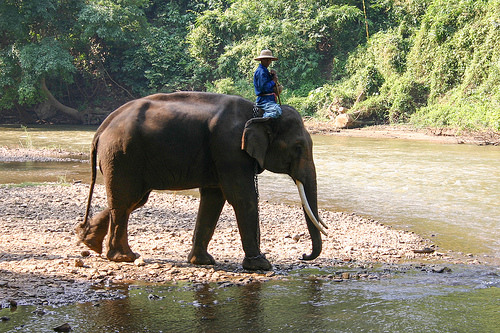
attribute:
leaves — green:
[0, 0, 499, 132]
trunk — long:
[298, 177, 323, 262]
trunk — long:
[292, 171, 324, 261]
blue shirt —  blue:
[252, 64, 279, 100]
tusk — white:
[293, 177, 330, 237]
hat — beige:
[255, 49, 278, 58]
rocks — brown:
[335, 221, 410, 265]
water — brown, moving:
[5, 118, 498, 249]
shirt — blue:
[251, 65, 283, 103]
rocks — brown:
[352, 224, 413, 275]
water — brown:
[1, 125, 498, 329]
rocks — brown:
[234, 275, 255, 287]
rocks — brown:
[329, 271, 338, 285]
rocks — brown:
[69, 248, 87, 271]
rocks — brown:
[80, 248, 92, 257]